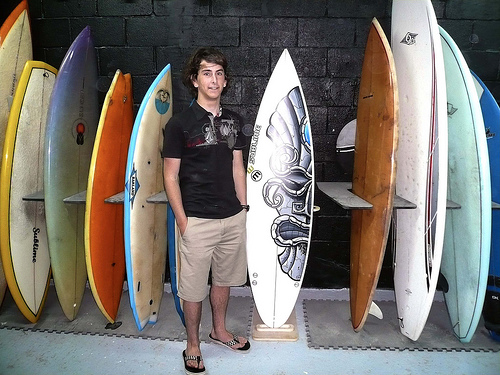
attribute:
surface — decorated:
[263, 85, 306, 307]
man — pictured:
[152, 45, 268, 373]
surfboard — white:
[240, 89, 300, 256]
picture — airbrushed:
[267, 153, 300, 247]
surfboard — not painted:
[351, 17, 398, 331]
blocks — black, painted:
[299, 19, 358, 46]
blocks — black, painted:
[181, 16, 237, 43]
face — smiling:
[189, 52, 239, 99]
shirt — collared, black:
[162, 99, 244, 221]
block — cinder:
[238, 18, 296, 43]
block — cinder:
[300, 17, 355, 48]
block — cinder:
[181, 15, 239, 45]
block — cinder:
[124, 17, 180, 47]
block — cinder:
[223, 44, 270, 75]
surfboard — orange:
[88, 65, 158, 324]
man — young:
[161, 45, 251, 372]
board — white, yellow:
[0, 42, 59, 330]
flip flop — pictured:
[178, 346, 209, 372]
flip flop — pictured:
[203, 326, 252, 353]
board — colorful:
[126, 63, 170, 331]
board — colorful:
[84, 68, 131, 322]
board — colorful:
[46, 28, 92, 321]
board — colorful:
[3, 60, 56, 321]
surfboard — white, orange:
[1, 2, 36, 142]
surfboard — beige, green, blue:
[40, 21, 100, 319]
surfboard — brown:
[348, 16, 400, 334]